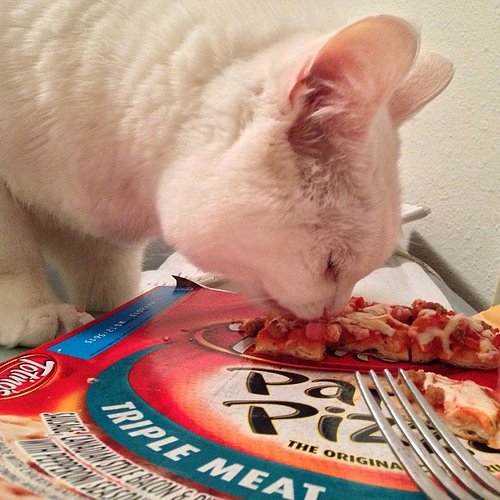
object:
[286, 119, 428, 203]
person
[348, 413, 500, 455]
writing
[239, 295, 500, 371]
pizza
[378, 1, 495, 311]
wall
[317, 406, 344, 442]
letter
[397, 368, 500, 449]
pizza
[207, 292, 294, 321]
whiskers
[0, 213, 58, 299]
legs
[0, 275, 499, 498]
box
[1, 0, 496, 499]
table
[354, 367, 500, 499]
fork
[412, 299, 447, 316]
meatball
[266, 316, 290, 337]
meatball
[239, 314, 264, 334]
meatball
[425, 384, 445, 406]
meatball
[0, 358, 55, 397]
logo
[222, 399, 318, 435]
letter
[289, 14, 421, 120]
ears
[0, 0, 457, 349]
cat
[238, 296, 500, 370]
slice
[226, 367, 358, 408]
writing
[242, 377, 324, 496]
writing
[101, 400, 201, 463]
writing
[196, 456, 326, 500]
writing